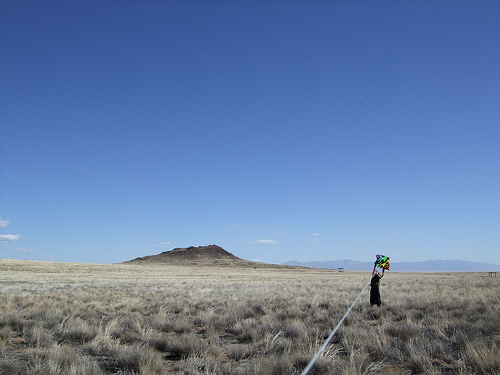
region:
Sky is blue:
[4, 3, 493, 243]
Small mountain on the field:
[125, 237, 259, 272]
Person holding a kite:
[359, 250, 396, 315]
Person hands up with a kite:
[364, 249, 393, 313]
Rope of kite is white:
[289, 280, 373, 372]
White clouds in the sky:
[1, 219, 29, 244]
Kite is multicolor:
[371, 247, 402, 273]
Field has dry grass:
[0, 271, 499, 373]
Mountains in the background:
[391, 256, 495, 274]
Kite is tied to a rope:
[294, 249, 393, 374]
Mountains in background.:
[106, 211, 496, 271]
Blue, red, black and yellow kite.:
[366, 246, 396, 277]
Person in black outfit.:
[361, 263, 386, 313]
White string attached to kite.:
[280, 266, 380, 369]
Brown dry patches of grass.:
[67, 271, 142, 332]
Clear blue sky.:
[295, 75, 480, 210]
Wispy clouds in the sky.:
[0, 0, 495, 245]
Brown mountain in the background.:
[111, 222, 281, 282]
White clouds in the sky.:
[0, 230, 26, 245]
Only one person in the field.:
[327, 217, 404, 327]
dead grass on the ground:
[101, 333, 161, 372]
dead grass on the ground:
[159, 330, 205, 355]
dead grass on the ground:
[281, 315, 308, 341]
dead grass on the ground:
[231, 316, 258, 343]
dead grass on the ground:
[300, 347, 327, 361]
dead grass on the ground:
[462, 334, 498, 368]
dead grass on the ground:
[31, 335, 83, 370]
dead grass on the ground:
[1, 299, 21, 330]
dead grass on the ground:
[286, 302, 306, 317]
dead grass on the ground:
[115, 295, 141, 335]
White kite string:
[292, 267, 369, 373]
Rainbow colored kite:
[372, 251, 394, 274]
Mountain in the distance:
[112, 236, 261, 268]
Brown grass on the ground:
[68, 302, 199, 344]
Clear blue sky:
[147, 122, 291, 179]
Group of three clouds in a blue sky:
[0, 214, 35, 264]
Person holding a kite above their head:
[362, 250, 397, 310]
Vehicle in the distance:
[335, 264, 348, 274]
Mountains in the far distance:
[276, 252, 498, 279]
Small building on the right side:
[484, 269, 498, 283]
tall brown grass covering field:
[41, 267, 221, 363]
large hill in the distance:
[125, 234, 293, 279]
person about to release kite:
[344, 243, 399, 320]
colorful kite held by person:
[365, 247, 403, 278]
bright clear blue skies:
[108, 47, 232, 142]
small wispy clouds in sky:
[241, 223, 328, 257]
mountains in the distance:
[307, 238, 497, 277]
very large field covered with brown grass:
[48, 265, 274, 360]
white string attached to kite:
[288, 265, 388, 370]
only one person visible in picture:
[333, 236, 405, 323]